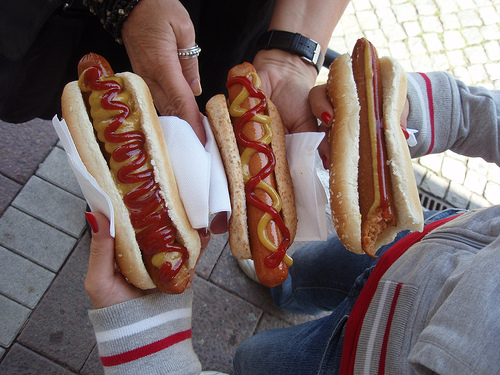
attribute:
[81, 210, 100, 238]
nail polish — red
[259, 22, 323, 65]
watchband — black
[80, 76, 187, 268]
mustard — heavily applied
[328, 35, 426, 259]
hot dog — topped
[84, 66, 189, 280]
ketchup — decorative, heavily applied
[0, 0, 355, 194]
person — woman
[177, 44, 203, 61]
ring — silver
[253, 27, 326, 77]
watch — black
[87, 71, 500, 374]
sweater — grey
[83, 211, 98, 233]
thumb nail — red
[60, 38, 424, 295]
hot dogs — numerous, dressed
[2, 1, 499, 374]
ground — brick pavers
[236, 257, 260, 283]
sneaker — white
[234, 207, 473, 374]
jeans — blue